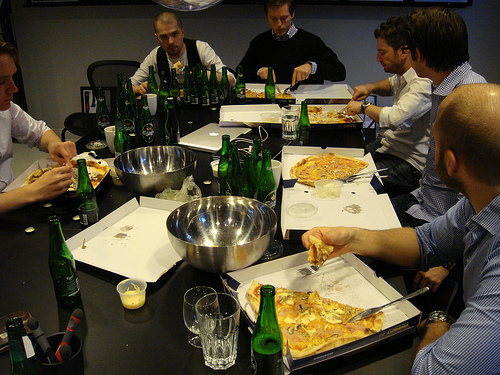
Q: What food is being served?
A: Pizza.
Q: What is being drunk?
A: Beer.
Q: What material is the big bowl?
A: Metal.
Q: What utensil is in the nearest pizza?
A: A knife.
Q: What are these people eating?
A: Pizza.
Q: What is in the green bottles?
A: Beer.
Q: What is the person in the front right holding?
A: A slice of pizza.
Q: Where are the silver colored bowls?
A: On the black table?.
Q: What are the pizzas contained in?
A: White boxes.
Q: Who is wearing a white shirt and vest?
A: The man near the head of the table on the left.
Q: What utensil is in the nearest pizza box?
A: A fork.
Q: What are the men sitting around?
A: A black table.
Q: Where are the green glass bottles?
A: On the table.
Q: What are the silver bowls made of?
A: Metal.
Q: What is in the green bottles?
A: Beer.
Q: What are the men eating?
A: Pizza.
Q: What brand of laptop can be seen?
A: Apple.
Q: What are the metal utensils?
A: Knife and fork.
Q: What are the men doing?
A: Eating pizza.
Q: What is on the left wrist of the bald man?
A: Watch.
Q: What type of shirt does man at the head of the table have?
A: Sweater.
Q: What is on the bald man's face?
A: Beard.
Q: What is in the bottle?
A: Beer.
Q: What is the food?
A: Pizza.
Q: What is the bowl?
A: Silver.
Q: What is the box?
A: Cardboard.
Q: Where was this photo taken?
A: At a restaurant.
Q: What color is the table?
A: Black.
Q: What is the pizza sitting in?
A: A cardboard box.